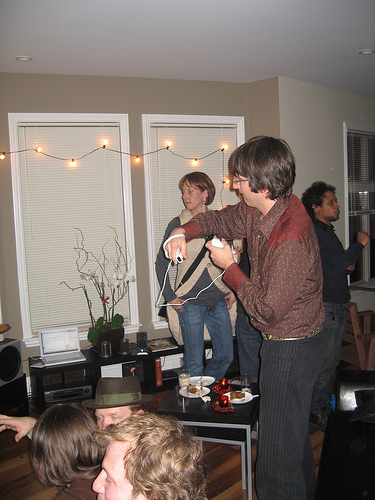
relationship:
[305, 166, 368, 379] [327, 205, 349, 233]
man with goatee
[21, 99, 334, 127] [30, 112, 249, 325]
lights on window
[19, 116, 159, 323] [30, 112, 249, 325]
blinds on window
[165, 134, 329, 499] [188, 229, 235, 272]
man holding controller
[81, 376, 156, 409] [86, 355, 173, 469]
fedora on head